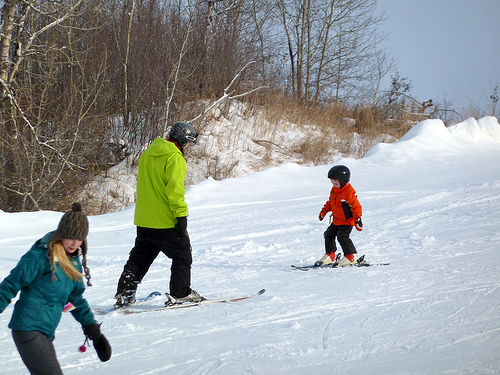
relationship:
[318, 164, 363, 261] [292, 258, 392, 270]
boy standing on skis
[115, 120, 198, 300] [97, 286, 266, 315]
man standing on skis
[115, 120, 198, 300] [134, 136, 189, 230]
man wearing jacket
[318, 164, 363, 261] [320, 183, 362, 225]
boy wearing coat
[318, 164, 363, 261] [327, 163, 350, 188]
boy wearing helmet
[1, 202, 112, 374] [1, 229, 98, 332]
woman wearing coat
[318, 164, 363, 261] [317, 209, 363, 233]
boy wearing mitts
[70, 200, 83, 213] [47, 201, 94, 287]
pom pom on top of hat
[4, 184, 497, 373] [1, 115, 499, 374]
ski tracks along snow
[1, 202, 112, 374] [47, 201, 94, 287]
woman wearing hat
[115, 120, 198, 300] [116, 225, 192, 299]
man wearing snow pants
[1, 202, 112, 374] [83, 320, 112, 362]
woman wearing glove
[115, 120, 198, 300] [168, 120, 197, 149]
man wearing helmet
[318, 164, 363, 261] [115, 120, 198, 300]
boy skiing towards man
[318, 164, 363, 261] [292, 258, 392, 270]
boy on top of skis